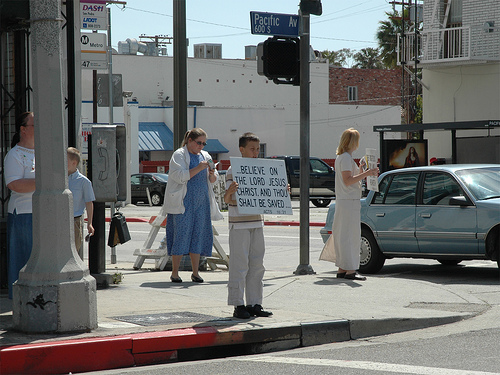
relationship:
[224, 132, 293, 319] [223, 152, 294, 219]
boy holding sign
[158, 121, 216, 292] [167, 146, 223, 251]
woman wearing dress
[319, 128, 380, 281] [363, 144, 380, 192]
woman holding sign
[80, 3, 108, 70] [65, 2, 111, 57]
metro sign has one metro sign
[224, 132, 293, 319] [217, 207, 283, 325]
boy wearing pants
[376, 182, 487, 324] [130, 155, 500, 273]
background has three background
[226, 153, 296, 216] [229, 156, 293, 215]
sign religious in sign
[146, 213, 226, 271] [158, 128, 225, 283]
barrier for safety behind woman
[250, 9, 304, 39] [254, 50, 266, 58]
sign for pacific av.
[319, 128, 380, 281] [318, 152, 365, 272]
woman in a dress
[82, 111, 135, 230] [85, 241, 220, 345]
pay phone mounted to sidewalk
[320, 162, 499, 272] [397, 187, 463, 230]
sedan four door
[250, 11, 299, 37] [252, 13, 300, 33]
sign with letters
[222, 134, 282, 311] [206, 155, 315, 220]
boy in corner holding a street sign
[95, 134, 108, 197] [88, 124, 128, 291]
coin operated payphone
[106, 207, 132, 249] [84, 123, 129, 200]
phone book hanging from a pay phone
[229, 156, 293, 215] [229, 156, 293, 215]
sign with a religious sign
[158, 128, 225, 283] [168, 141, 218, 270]
woman in a dress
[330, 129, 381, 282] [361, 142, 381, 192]
woman standing on a corner holding a sign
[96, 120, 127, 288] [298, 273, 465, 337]
payphone booth on street corner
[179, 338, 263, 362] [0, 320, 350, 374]
drain water in street curb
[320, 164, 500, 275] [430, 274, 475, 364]
sedan on street near corner